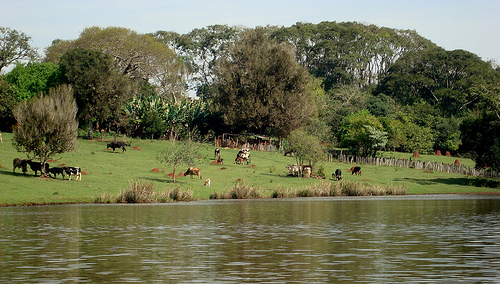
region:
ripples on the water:
[54, 205, 497, 283]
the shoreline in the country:
[16, 173, 498, 218]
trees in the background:
[12, 19, 497, 114]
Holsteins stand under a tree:
[5, 82, 90, 189]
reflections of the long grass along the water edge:
[146, 198, 498, 226]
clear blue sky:
[430, 5, 499, 35]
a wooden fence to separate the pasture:
[329, 153, 494, 174]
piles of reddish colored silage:
[412, 138, 470, 165]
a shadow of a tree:
[397, 150, 497, 201]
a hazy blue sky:
[27, 2, 499, 32]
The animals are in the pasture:
[23, 143, 394, 203]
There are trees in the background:
[206, 33, 493, 150]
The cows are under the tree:
[6, 127, 110, 185]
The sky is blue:
[50, 18, 459, 118]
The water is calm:
[216, 213, 419, 282]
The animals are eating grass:
[183, 146, 372, 203]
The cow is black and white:
[51, 158, 89, 184]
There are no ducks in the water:
[113, 170, 443, 255]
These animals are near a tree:
[280, 158, 400, 191]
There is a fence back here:
[354, 151, 498, 188]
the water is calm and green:
[1, 191, 498, 282]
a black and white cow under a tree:
[49, 165, 80, 179]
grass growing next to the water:
[93, 180, 408, 201]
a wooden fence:
[161, 129, 499, 181]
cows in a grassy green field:
[1, 127, 498, 204]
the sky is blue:
[0, 0, 499, 103]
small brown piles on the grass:
[148, 167, 160, 173]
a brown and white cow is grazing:
[182, 166, 202, 178]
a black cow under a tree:
[26, 157, 49, 174]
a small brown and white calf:
[201, 177, 211, 187]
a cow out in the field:
[64, 162, 84, 181]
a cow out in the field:
[6, 150, 28, 174]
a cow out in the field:
[28, 156, 48, 174]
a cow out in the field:
[175, 160, 205, 181]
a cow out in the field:
[107, 135, 126, 153]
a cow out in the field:
[236, 149, 250, 163]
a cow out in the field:
[212, 146, 224, 156]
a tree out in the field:
[11, 82, 84, 179]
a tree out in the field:
[203, 35, 310, 144]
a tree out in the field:
[161, 125, 209, 181]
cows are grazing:
[13, 140, 363, 187]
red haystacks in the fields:
[44, 138, 460, 176]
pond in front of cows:
[1, 192, 498, 282]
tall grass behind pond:
[94, 180, 406, 204]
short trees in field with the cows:
[10, 46, 330, 182]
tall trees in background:
[0, 21, 498, 158]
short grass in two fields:
[0, 130, 499, 205]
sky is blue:
[0, 0, 499, 100]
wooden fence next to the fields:
[212, 132, 499, 179]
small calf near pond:
[203, 177, 211, 187]